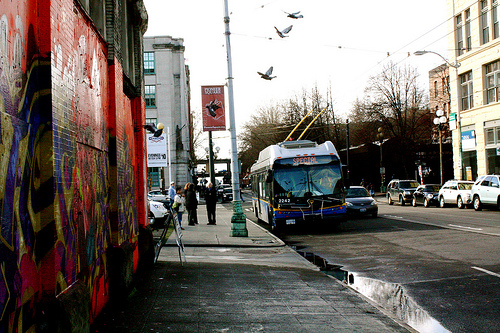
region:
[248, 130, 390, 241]
bus driving down the road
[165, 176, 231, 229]
people walking down the sidewalk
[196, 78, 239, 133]
red sign attached to the pole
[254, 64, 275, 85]
bird in fight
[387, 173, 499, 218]
row of cars parallel parked along the side of the street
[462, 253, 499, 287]
white line painted on the street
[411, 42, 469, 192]
light post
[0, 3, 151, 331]
mural on the wall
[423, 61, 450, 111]
top of a brown building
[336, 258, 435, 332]
water along the side of the street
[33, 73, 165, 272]
Blue, yellow and red graffiti on the wall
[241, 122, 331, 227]
An electric bus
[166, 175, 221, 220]
People standing on the sidewalk.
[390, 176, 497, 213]
Cars parked on the roadside.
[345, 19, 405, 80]
The sky is white.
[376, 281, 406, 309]
a poodle of water on the road.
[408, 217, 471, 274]
A concrete road.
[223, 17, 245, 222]
A metal beam with a orange, white and black sign on it.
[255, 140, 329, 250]
the bus is white and blue with a yellow stripe.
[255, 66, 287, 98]
A bird flying over the bus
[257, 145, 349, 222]
this is a bus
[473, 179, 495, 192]
this is a car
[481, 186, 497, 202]
the car is white in color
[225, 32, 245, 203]
this is a pole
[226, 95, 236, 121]
the pole is white in color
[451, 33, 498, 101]
this is a building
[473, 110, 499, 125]
this is the wall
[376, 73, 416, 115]
this is a tree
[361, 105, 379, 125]
the leaves are green in color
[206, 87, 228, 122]
this is a notice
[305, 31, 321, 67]
this is the sky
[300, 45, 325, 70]
the sky is bright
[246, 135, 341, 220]
this is a bus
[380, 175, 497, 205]
the cars are parked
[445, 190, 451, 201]
the car is grey in color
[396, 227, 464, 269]
this is the road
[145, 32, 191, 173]
this is a building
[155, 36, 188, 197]
the wall is grey in color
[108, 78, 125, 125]
the wall is red in color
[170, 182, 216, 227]
some people on the pavement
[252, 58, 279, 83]
Birds flying in the air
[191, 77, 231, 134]
Sign attached to utility pole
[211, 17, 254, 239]
Utility pole anchored in sidewalk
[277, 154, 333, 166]
Electronic sign on passenger bus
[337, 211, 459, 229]
Shadow on road cast by a passenger bus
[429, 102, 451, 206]
Streetlights anchored to the sidewalk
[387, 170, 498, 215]
Cars parked on the street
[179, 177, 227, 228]
Travelers waiting for a bus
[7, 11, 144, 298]
Graffiti painted on a wall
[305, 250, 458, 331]
Puddle in the gutter of street